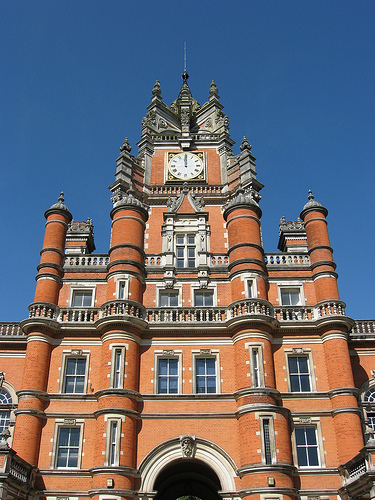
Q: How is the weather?
A: It is clear.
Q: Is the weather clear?
A: Yes, it is clear.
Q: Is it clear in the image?
A: Yes, it is clear.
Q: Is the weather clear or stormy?
A: It is clear.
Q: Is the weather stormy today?
A: No, it is clear.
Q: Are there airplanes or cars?
A: No, there are no cars or airplanes.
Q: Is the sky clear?
A: Yes, the sky is clear.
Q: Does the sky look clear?
A: Yes, the sky is clear.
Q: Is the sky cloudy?
A: No, the sky is clear.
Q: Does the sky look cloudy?
A: No, the sky is clear.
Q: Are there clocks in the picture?
A: Yes, there is a clock.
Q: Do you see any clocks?
A: Yes, there is a clock.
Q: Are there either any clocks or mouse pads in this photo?
A: Yes, there is a clock.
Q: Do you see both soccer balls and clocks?
A: No, there is a clock but no soccer balls.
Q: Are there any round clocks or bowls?
A: Yes, there is a round clock.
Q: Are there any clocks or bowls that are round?
A: Yes, the clock is round.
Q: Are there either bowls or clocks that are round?
A: Yes, the clock is round.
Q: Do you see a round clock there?
A: Yes, there is a round clock.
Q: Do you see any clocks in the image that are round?
A: Yes, there is a clock that is round.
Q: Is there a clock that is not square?
A: Yes, there is a round clock.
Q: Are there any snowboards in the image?
A: No, there are no snowboards.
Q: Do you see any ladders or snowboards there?
A: No, there are no snowboards or ladders.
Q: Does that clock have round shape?
A: Yes, the clock is round.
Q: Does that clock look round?
A: Yes, the clock is round.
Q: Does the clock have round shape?
A: Yes, the clock is round.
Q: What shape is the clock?
A: The clock is round.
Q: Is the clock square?
A: No, the clock is round.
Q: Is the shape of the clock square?
A: No, the clock is round.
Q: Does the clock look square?
A: No, the clock is round.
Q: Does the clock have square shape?
A: No, the clock is round.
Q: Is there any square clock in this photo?
A: No, there is a clock but it is round.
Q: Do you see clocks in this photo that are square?
A: No, there is a clock but it is round.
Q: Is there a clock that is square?
A: No, there is a clock but it is round.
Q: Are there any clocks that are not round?
A: No, there is a clock but it is round.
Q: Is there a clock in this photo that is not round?
A: No, there is a clock but it is round.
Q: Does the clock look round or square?
A: The clock is round.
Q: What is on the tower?
A: The clock is on the tower.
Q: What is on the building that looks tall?
A: The clock is on the tower.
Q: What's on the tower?
A: The clock is on the tower.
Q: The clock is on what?
A: The clock is on the tower.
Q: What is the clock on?
A: The clock is on the tower.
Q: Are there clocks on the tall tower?
A: Yes, there is a clock on the tower.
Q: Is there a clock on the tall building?
A: Yes, there is a clock on the tower.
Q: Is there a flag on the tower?
A: No, there is a clock on the tower.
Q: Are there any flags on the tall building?
A: No, there is a clock on the tower.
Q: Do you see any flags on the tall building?
A: No, there is a clock on the tower.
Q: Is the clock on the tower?
A: Yes, the clock is on the tower.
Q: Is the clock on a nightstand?
A: No, the clock is on the tower.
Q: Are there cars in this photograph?
A: No, there are no cars.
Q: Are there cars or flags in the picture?
A: No, there are no cars or flags.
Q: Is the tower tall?
A: Yes, the tower is tall.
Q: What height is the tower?
A: The tower is tall.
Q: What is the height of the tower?
A: The tower is tall.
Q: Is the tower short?
A: No, the tower is tall.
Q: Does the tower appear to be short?
A: No, the tower is tall.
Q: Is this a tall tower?
A: Yes, this is a tall tower.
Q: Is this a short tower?
A: No, this is a tall tower.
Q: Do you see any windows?
A: Yes, there is a window.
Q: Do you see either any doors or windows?
A: Yes, there is a window.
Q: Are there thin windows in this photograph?
A: Yes, there is a thin window.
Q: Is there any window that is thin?
A: Yes, there is a window that is thin.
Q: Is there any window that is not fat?
A: Yes, there is a thin window.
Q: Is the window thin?
A: Yes, the window is thin.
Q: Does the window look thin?
A: Yes, the window is thin.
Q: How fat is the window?
A: The window is thin.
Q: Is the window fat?
A: No, the window is thin.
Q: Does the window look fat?
A: No, the window is thin.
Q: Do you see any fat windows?
A: No, there is a window but it is thin.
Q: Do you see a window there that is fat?
A: No, there is a window but it is thin.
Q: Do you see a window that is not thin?
A: No, there is a window but it is thin.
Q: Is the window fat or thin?
A: The window is thin.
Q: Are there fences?
A: No, there are no fences.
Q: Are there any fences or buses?
A: No, there are no fences or buses.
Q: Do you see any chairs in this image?
A: No, there are no chairs.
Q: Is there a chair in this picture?
A: No, there are no chairs.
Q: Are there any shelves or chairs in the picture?
A: No, there are no chairs or shelves.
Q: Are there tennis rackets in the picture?
A: No, there are no tennis rackets.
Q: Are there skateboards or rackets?
A: No, there are no rackets or skateboards.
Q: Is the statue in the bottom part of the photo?
A: Yes, the statue is in the bottom of the image.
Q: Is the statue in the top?
A: No, the statue is in the bottom of the image.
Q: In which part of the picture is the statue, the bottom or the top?
A: The statue is in the bottom of the image.